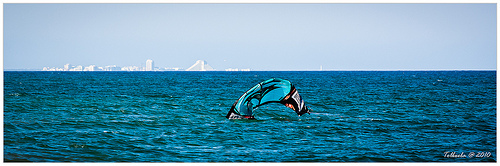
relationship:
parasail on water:
[232, 73, 310, 123] [352, 106, 405, 118]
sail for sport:
[226, 80, 308, 125] [220, 72, 315, 138]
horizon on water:
[2, 67, 496, 72] [4, 80, 493, 163]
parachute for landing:
[229, 76, 330, 118] [202, 109, 347, 149]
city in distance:
[40, 56, 251, 71] [8, 45, 498, 80]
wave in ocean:
[91, 130, 155, 154] [76, 80, 207, 125]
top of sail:
[231, 71, 310, 96] [232, 83, 306, 120]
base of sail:
[234, 104, 265, 121] [230, 70, 314, 124]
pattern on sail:
[240, 77, 279, 105] [225, 76, 308, 121]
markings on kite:
[255, 81, 273, 102] [220, 78, 306, 129]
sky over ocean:
[1, 0, 495, 71] [2, 71, 494, 164]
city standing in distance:
[40, 56, 251, 71] [40, 51, 220, 78]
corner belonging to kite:
[228, 112, 241, 118] [219, 71, 312, 122]